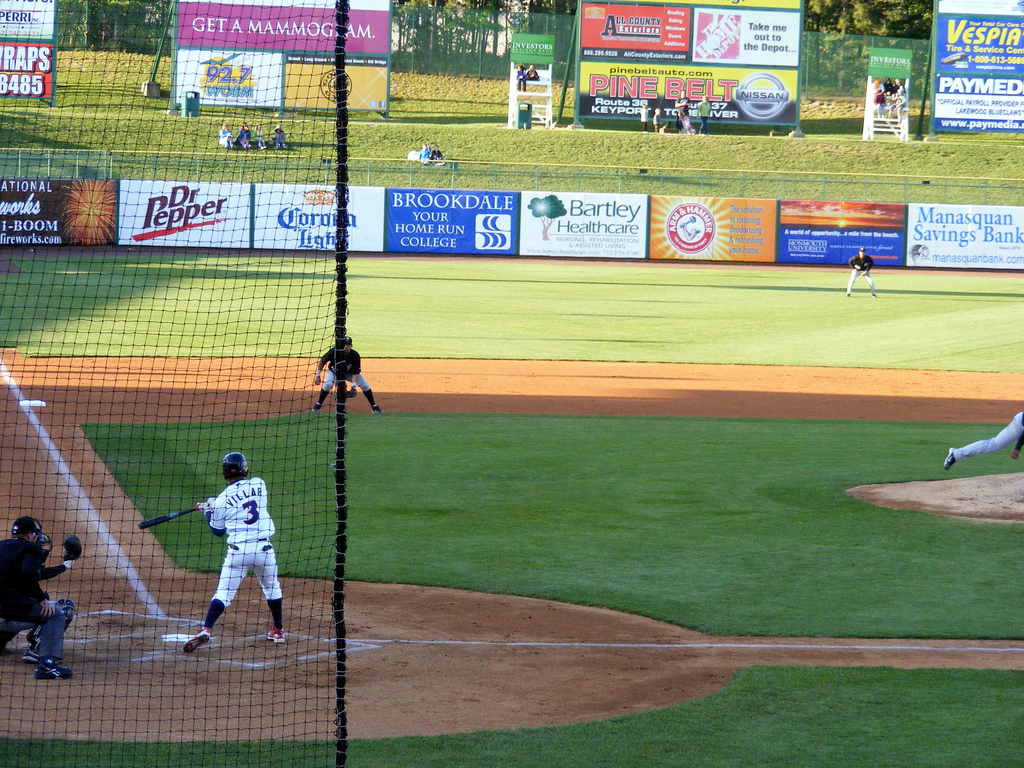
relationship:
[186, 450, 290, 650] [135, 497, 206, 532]
catcher holding bat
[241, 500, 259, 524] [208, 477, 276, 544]
number on jersey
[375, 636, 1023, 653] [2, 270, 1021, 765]
line in field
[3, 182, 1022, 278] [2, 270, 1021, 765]
advertisements in field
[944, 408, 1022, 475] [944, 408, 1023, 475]
leg of leg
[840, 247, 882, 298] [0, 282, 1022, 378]
man in field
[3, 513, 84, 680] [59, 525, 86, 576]
person wearing glove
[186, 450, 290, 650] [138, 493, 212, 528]
catcher swinging bat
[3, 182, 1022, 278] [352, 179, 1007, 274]
advertisements on wall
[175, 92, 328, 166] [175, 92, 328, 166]
people on grassy hill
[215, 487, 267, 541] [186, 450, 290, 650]
number on catcher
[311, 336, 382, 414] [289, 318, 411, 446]
dirt on dirt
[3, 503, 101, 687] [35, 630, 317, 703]
person on ground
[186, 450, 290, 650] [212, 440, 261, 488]
catcher wearing a helmet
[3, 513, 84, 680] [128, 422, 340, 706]
person behind catcher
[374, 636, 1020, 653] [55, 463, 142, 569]
line made of chalk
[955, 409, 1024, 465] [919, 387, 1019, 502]
clothing of clothing